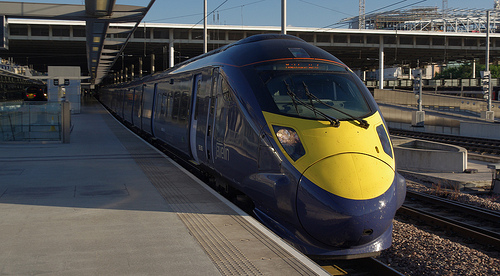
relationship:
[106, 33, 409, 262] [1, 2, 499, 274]
train at a station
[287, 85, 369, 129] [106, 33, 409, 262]
wipers are on train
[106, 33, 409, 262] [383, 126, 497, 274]
train on tracks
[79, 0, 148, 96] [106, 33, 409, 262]
awning over train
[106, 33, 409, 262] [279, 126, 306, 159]
train has headlight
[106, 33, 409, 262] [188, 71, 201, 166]
train has door